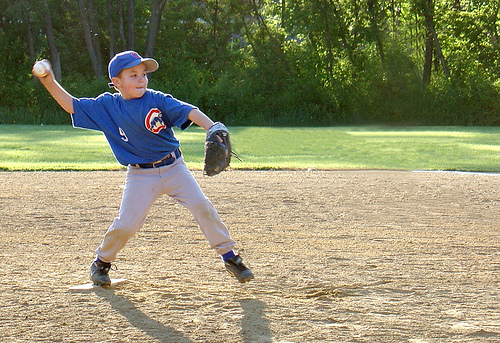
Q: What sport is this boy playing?
A: Baseball.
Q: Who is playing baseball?
A: A boy.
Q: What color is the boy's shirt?
A: Blue.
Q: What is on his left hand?
A: Glove.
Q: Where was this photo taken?
A: Baseball diamond.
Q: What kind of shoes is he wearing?
A: Cleats.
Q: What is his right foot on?
A: Pitcher's mound.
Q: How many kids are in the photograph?
A: One.